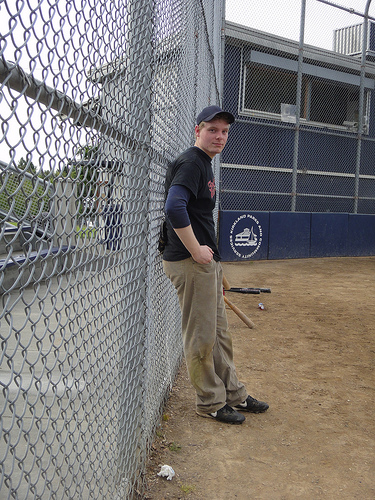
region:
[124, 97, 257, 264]
Man leaning against a chain link fence.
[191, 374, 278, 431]
Man wearing black and white shoes.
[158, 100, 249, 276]
Man with his hand in his pocket.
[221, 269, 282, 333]
Baseball bats ready for the game.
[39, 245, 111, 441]
Chain link fence around the field.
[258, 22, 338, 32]
Pale sky far above.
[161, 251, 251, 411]
Light tan chino pants stained below the knee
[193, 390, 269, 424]
Twin black shoes with a white nike swoosh on the side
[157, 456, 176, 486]
White crumpled paper on the ground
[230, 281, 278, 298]
Twin dark colored baseball bats on the tan ground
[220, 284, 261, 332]
Light brown wooden baseball bat leaning against the fence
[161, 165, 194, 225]
Longer arm of a blue shirt coming from under a t shirt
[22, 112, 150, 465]
Rings of a gray metal fence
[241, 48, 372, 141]
Window of a blue painted building with a metal frame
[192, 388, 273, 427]
Man wearing shoes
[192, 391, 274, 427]
Man is wearing shoes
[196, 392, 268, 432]
Man wearing black and white shoes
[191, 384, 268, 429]
Man is wearing white and black shoes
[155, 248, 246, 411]
Man wearing pants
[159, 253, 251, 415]
Man is wearing pants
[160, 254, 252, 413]
Man wearing brown pants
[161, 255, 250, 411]
Man is wearing brown pants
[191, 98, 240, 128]
Man is wearing a black hat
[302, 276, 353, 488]
The ground is the color brown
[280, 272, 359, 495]
The ground is made of dirt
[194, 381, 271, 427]
The shoes of the man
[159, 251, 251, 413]
The man has on pants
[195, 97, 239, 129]
The man is wearing a hat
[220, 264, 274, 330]
The bats are in the field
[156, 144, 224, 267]
The man has on a black shirt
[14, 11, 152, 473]
The gate is made of metal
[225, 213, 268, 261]
The logo on the gate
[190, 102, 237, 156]
The head of the man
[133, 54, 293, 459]
man leaning on fence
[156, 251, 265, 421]
man wearing khaki pants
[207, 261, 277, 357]
man holding baseball bat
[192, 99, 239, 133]
man wearing a baseball cap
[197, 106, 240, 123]
man wearing a blue cap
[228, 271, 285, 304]
bats laying on the floor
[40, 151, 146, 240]
chain link fence surrounding field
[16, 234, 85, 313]
chain link fence surrounding field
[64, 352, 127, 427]
chain link fence surrounding field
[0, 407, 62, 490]
chain link fence surrounding field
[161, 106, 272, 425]
Young man leaning against a fence.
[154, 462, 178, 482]
White piece of trash on the ground.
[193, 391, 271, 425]
Black shoes on a man by a fence.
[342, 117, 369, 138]
Two cameras behind the fence.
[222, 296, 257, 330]
Wooden bat closest to the man.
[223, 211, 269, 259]
White logo on a blue wall.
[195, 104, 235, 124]
Blue hat on the head of the man by the fence.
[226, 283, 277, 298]
Two black bats laying on the ground.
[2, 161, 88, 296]
Set of bleachers behind the fence.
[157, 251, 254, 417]
A pair of brown pants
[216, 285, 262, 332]
A wooden brown baseball bat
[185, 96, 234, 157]
Black hat on a man's head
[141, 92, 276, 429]
A man leaning against a fence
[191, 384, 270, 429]
A pair of black sneakers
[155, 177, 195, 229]
A navy blue sleeve of a shirt